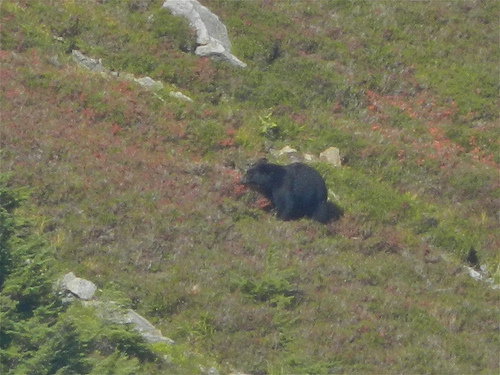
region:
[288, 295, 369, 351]
part of some grass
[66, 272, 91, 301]
part of a stone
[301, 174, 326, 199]
stomach of a bear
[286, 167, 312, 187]
back of a bear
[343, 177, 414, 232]
part of some green plant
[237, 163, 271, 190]
head of a bear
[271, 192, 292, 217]
front leg of a bear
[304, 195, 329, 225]
hind leg of a bear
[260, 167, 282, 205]
neck of a bear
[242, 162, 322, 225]
part of a bear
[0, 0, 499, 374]
Entire green grassy field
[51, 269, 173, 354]
Gray rock below and to the right of the small black animal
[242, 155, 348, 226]
Small black furry animal in a grassy field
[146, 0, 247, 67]
Large gray rock above the animal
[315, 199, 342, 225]
Furry black tail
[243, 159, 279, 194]
Small black animal's head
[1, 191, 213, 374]
Very bushy green patch in front of the rock below the animal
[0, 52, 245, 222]
Dry brownish grass in front of the black animal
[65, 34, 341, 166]
Row of smaller gray rocks above the black animal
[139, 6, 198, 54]
Patch of green partially covering the large rock above the black animal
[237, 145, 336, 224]
black bear on hill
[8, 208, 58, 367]
green and brown bushes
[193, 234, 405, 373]
green and brown bushes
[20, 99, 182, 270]
green and brown bushes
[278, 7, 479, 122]
green and brown bushes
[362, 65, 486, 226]
green and brown bushes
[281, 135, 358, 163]
gray rocks on hill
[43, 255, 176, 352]
gray rocks on hill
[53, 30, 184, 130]
gray rocks on hill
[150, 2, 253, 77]
gray rocks on hill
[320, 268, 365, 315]
part of some grass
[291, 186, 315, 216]
stomach of a bear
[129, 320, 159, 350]
part of a stone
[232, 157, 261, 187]
head of a bear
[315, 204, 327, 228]
part of a hind leg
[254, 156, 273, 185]
head of a bear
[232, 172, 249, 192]
mouth of a bear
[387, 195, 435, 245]
part of some green plant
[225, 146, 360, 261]
bear is black and walking